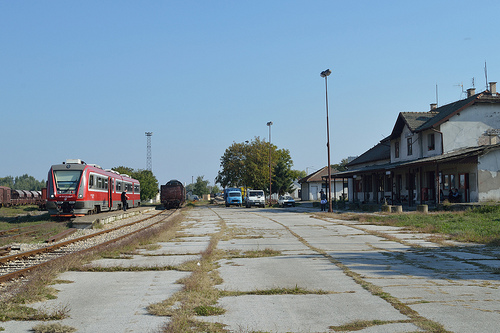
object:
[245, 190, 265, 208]
truck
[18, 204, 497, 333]
road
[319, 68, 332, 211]
light pole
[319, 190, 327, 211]
man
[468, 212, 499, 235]
grass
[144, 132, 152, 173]
pole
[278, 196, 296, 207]
vehicles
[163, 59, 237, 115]
sky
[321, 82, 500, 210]
house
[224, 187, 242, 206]
truck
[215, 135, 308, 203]
tree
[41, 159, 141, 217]
train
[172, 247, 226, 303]
patch